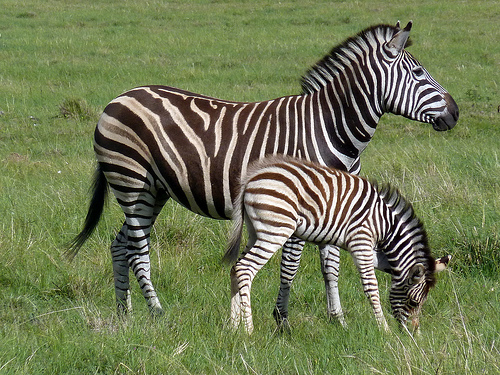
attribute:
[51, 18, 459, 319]
zebra — striped, black, white, adult, standing, large, brown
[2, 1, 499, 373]
grass — green, short, tall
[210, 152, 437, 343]
zebra — black, white, grazing, striped, feeding, baby, brown, small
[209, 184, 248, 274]
tail — swinging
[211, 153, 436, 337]
fur — brown, white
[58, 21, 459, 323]
fur — brown, white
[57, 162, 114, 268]
tail — black